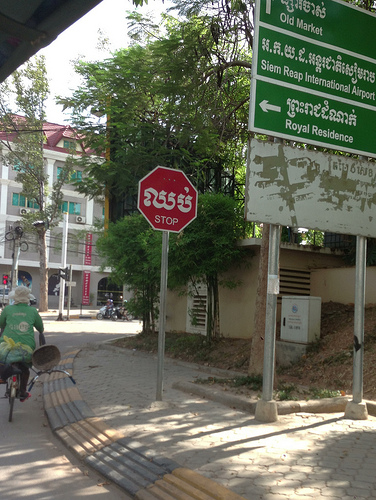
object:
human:
[0, 285, 46, 387]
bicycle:
[0, 364, 26, 422]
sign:
[248, 0, 376, 158]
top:
[0, 302, 45, 368]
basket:
[32, 344, 61, 371]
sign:
[137, 165, 199, 234]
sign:
[244, 137, 376, 238]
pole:
[156, 231, 169, 402]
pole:
[262, 224, 281, 401]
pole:
[353, 236, 367, 403]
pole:
[58, 212, 68, 317]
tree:
[38, 232, 48, 312]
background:
[0, 109, 134, 306]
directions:
[259, 100, 282, 113]